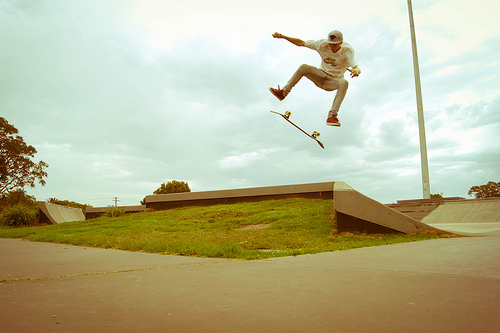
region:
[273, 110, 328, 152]
skate board in air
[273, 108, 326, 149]
upside down skate board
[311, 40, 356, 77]
white cotton tee shirt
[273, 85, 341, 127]
red and white sneakers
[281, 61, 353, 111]
tan colored denim jeans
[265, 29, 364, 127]
man wearing tan hat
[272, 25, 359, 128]
man doing skate board tricks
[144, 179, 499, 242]
tan wood skate board ramp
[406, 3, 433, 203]
white metal flag pole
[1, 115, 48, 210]
tree with green leaves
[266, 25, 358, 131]
man doing skateboard tricks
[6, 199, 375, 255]
green grass on hill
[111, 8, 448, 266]
man in mid air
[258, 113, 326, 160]
skateboard in mid air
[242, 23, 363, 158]
man riding a skateboard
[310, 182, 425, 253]
small concrete skate jump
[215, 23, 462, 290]
man going of skate jump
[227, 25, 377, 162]
man kick flipping in air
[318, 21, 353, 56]
silver baseball hat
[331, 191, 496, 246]
skate board ramp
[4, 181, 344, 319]
grass field next to concrete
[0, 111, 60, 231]
trees by the grass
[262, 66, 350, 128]
Legs of a person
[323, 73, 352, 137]
Leg of a person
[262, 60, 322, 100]
Leg of a person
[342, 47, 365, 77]
Hand of a person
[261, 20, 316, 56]
Hand of a person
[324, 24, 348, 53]
Head of a person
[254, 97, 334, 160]
This is a skating board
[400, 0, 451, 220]
This is a pole post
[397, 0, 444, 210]
A tall electric pole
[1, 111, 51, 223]
This is a tree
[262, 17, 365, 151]
man jumping off skateboard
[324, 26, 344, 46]
light colored hat of skateboarder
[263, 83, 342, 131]
shoe and laces of skateboard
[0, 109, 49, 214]
tree on the left side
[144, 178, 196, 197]
green busn above ramp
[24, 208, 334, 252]
patch of grass in middle of ramp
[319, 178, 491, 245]
ramp skateboarder is jumping off of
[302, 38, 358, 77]
white short sleeve shirt of skateboarder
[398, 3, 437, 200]
white pole in background